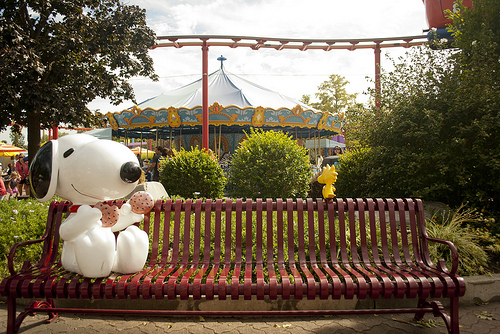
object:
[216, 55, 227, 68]
cross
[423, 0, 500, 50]
coaster car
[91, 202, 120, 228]
cookies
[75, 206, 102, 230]
hands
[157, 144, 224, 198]
bush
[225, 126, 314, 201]
bush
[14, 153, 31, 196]
people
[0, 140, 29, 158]
tent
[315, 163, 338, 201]
statue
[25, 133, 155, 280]
dog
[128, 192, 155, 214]
cookie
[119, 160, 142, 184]
nose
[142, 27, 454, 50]
track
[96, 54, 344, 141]
tent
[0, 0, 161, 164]
tree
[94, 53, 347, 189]
carousel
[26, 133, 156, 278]
snoopy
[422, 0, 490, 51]
rollercoaster car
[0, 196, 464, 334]
bench